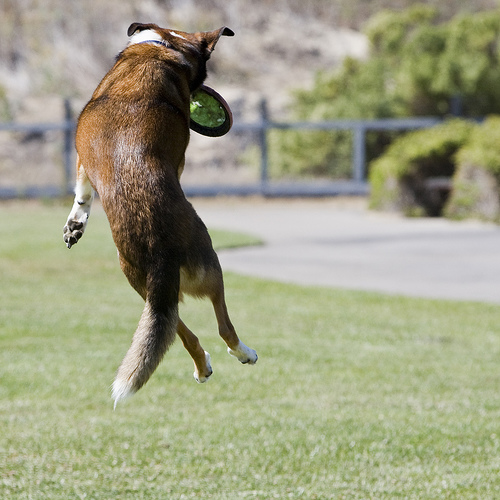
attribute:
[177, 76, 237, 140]
frisbee — green, black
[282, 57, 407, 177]
tree — small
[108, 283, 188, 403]
dog's tail — white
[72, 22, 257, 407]
dog — brown, white, airborne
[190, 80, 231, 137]
frisbee — small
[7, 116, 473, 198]
fence — blue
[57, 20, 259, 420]
dog — brown, white, tan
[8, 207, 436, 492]
grass — green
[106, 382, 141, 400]
tip — white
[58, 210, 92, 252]
dog's paws — white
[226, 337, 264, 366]
dog's paws — white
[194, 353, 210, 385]
dog's paws — white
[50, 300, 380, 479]
grass — green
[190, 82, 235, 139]
frisbee — green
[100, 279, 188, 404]
tail — bushy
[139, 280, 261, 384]
legs — back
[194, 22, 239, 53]
ear — brown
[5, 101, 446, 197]
fence — blue, distant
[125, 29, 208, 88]
neck — white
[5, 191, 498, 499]
grass — small, tan, green, manicured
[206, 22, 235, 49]
ear — droopy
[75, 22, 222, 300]
coat — shiny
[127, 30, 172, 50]
patch — white